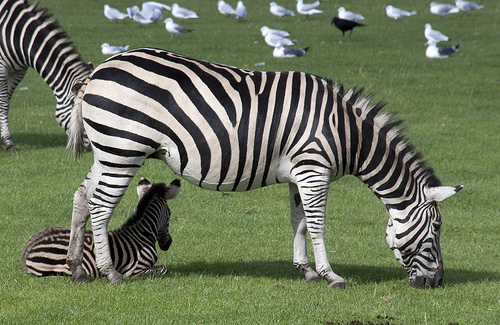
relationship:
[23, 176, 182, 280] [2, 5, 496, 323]
zebra in grass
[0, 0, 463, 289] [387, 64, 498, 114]
three zebras on grass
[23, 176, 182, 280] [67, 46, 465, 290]
zebra next to h animal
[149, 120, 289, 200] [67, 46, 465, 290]
belly of animal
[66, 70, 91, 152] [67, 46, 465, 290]
tail of animal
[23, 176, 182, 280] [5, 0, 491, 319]
zebra in a field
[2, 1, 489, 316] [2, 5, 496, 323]
zebras eating grass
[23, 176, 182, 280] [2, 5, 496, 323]
zebra laying in grass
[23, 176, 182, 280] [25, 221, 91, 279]
zebra has dirt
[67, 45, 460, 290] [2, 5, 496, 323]
animal on grass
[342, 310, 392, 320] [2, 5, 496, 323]
droppings on grass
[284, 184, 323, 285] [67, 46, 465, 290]
spot on animal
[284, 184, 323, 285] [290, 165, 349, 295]
spot on leg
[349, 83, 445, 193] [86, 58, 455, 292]
hair on zebra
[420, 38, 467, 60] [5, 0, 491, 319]
bird in field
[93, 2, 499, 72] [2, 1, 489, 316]
birds near zebras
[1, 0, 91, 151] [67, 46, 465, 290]
zebra obscuring face of animal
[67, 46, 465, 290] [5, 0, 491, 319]
animal on field